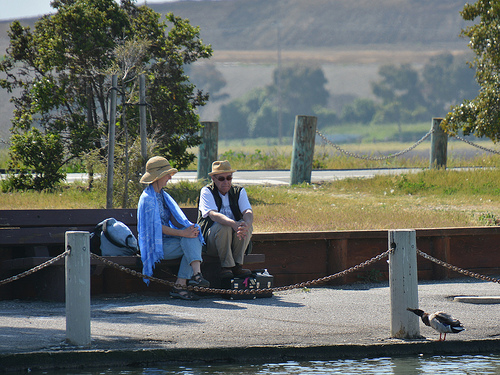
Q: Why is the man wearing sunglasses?
A: It's sunny.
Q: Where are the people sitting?
A: On a bench.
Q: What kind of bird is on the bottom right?
A: A duck.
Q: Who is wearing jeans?
A: The woman.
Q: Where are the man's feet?
A: On the tool case.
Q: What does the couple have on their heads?
A: Hats.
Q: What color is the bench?
A: Brown.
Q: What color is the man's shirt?
A: White.